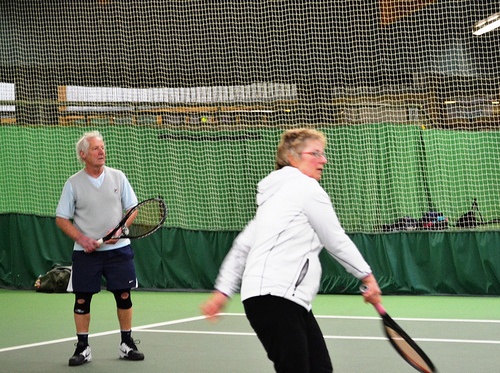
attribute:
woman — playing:
[193, 104, 408, 369]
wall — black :
[412, 116, 457, 161]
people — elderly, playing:
[39, 122, 444, 372]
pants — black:
[226, 295, 348, 372]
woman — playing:
[192, 115, 448, 370]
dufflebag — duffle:
[36, 264, 76, 292]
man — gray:
[51, 124, 146, 362]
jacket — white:
[212, 159, 362, 306]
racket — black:
[351, 282, 443, 371]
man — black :
[51, 129, 162, 349]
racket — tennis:
[85, 179, 169, 261]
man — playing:
[62, 126, 156, 366]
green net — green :
[0, 0, 500, 297]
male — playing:
[51, 129, 145, 365]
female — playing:
[197, 126, 383, 371]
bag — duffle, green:
[33, 259, 73, 293]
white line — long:
[129, 325, 498, 349]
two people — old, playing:
[47, 125, 372, 302]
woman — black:
[232, 151, 386, 368]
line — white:
[1, 314, 218, 354]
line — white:
[137, 327, 499, 345]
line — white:
[221, 311, 499, 323]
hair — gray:
[273, 127, 326, 169]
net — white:
[0, 0, 495, 233]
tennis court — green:
[4, 290, 497, 371]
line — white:
[201, 285, 483, 331]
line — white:
[150, 318, 482, 371]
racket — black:
[91, 204, 168, 246]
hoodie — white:
[264, 169, 334, 307]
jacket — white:
[204, 155, 359, 285]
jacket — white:
[218, 170, 370, 313]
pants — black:
[233, 285, 347, 372]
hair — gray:
[79, 125, 90, 159]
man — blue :
[45, 123, 157, 372]